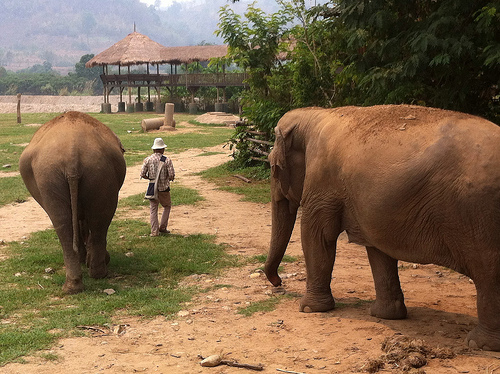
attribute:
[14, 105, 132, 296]
elephant — walking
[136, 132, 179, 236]
man — walking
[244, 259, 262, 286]
rock — grey, dirt, hut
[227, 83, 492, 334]
elephant — large, covered, walking, back, toenail, long, next, brown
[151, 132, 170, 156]
hat — white, brown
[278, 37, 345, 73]
leave — green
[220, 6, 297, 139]
tree — large, row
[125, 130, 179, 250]
man — walking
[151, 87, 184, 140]
structure — wooden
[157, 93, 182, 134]
post — wooden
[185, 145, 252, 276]
walkway — covered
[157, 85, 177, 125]
pillar — concrete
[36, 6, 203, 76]
mountain — background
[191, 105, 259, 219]
path — dirt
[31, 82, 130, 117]
fence — wood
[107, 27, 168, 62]
roof — thatched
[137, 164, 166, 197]
bag — gray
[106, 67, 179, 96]
deck — wooden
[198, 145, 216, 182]
sand — brown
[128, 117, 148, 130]
grass — green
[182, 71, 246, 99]
bridge — wood